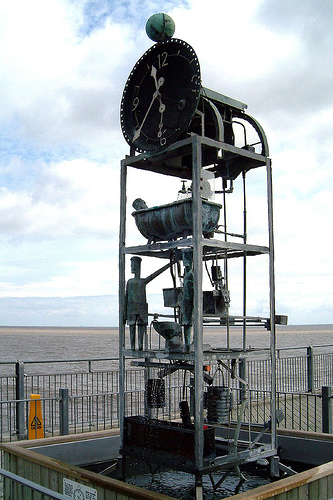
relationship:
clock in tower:
[114, 38, 202, 156] [96, 10, 297, 494]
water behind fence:
[0, 324, 332, 435] [2, 345, 332, 437]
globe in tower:
[139, 2, 171, 39] [120, 10, 298, 330]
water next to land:
[0, 324, 332, 435] [17, 311, 89, 335]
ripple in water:
[0, 324, 333, 431] [0, 324, 332, 435]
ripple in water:
[31, 377, 101, 381] [0, 324, 332, 435]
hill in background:
[25, 261, 86, 325] [20, 282, 90, 320]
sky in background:
[23, 182, 86, 283] [20, 282, 90, 320]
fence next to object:
[2, 345, 332, 437] [55, 386, 73, 433]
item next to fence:
[20, 385, 49, 434] [2, 345, 332, 437]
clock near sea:
[120, 38, 202, 154] [43, 331, 89, 360]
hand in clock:
[132, 76, 165, 143] [103, 35, 208, 161]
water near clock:
[0, 324, 332, 435] [115, 39, 208, 152]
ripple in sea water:
[0, 324, 333, 431] [0, 325, 332, 422]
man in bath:
[131, 195, 151, 210] [128, 195, 224, 241]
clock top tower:
[120, 38, 202, 154] [88, 11, 313, 476]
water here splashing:
[98, 461, 274, 499] [126, 371, 185, 469]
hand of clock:
[148, 66, 166, 107] [120, 39, 201, 154]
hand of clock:
[129, 76, 165, 142] [120, 39, 201, 154]